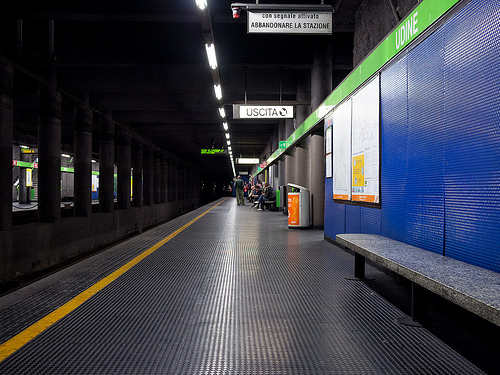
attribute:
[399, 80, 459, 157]
wall — blue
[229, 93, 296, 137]
sign — orange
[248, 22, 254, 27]
letter — black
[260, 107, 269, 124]
letter — black 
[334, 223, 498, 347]
bench — empty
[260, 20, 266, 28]
letter — black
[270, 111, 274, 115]
letter — black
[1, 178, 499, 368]
train platform — empty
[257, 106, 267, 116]
letter — black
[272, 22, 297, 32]
letter — black 